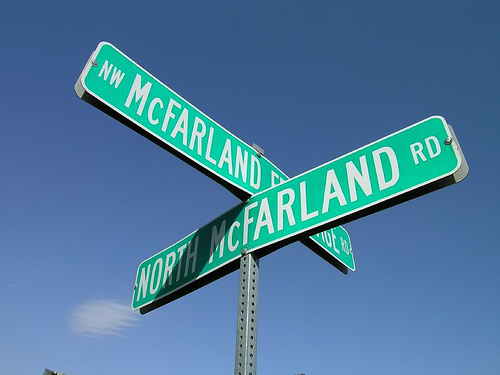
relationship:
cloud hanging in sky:
[68, 299, 143, 339] [2, 2, 484, 371]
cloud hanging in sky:
[68, 299, 143, 339] [19, 10, 472, 344]